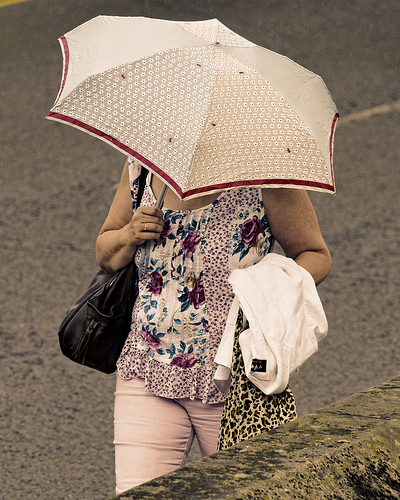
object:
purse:
[58, 166, 152, 375]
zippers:
[110, 277, 118, 287]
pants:
[112, 375, 226, 494]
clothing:
[212, 253, 328, 396]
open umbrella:
[44, 14, 343, 207]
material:
[216, 306, 297, 450]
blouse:
[115, 156, 275, 405]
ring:
[144, 222, 147, 231]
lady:
[58, 155, 333, 496]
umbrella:
[44, 14, 339, 281]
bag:
[57, 165, 149, 375]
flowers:
[136, 209, 212, 369]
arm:
[259, 188, 331, 288]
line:
[43, 43, 341, 203]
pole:
[156, 182, 168, 209]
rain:
[0, 0, 400, 500]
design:
[43, 14, 340, 205]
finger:
[137, 222, 163, 232]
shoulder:
[124, 156, 161, 187]